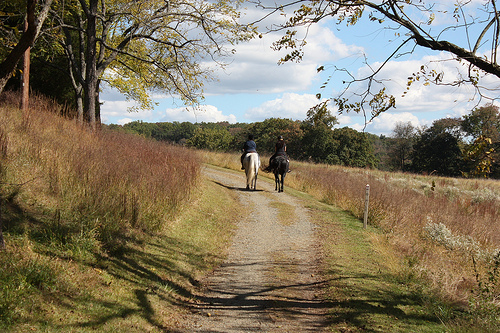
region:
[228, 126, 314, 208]
Two horses walk down a trail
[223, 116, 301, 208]
Two people ride horses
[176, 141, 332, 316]
The trail is dirt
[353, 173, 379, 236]
White pole on side of trail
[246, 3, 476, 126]
Trees above the trail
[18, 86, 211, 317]
Tall green and brown bushes on sides of trail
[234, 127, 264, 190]
The horse is white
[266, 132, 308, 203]
The horse is black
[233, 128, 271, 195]
The rider is wearing a blue shirt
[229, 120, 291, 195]
The riders are wearing helmets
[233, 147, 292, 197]
black and white horses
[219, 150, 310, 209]
black and white horses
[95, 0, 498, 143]
a blue sky with puffy clouds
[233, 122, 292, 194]
two horses with riders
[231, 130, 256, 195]
rider on a white horse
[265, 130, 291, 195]
rider on a black horse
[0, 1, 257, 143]
a group of trees with green leaves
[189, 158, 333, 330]
a dirt road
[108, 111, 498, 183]
a ridge of trees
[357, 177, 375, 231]
a white post next to road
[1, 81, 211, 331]
tall grass beside road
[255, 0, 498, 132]
tree branch with leaves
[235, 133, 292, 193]
two horses walking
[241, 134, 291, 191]
people riding horses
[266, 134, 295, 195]
black horse with a person on it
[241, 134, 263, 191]
white horse with a person on it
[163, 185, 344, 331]
a dirt road in the country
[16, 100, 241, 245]
tall grass on side of dirt road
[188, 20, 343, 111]
white clouds in the sky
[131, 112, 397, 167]
green, yellow and orange leaves on trees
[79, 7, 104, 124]
brownish tree bark on tree trunk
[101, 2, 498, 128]
blue sky with clouds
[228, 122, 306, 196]
two persons riding a horse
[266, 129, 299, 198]
person rides a black horse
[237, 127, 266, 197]
person rides a white horse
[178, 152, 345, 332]
road is not paved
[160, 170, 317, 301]
road has patches of grass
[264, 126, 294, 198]
man wearing black cloths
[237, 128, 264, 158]
person wearing blue clotsh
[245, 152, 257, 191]
tail of white horse is long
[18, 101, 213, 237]
grass is tall on left side of road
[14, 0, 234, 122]
a tree with yellow leaves